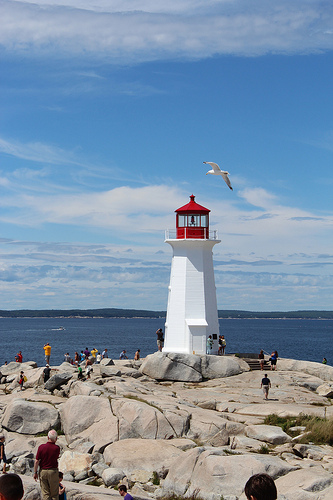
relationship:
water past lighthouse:
[2, 316, 332, 369] [161, 194, 220, 356]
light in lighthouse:
[188, 215, 195, 225] [161, 194, 220, 356]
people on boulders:
[18, 371, 26, 390] [1, 353, 333, 499]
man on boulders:
[260, 373, 272, 400] [1, 353, 333, 499]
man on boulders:
[156, 328, 164, 351] [1, 353, 333, 499]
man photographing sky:
[154, 328, 163, 352] [0, 1, 332, 308]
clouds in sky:
[53, 193, 177, 229] [0, 1, 332, 308]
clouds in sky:
[0, 0, 333, 307] [0, 1, 332, 308]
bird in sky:
[201, 156, 238, 195] [31, 114, 228, 199]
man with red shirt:
[32, 428, 61, 498] [35, 444, 60, 470]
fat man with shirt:
[39, 339, 56, 368] [38, 342, 54, 357]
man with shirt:
[253, 368, 283, 406] [257, 378, 272, 388]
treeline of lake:
[0, 307, 165, 317] [1, 315, 331, 371]